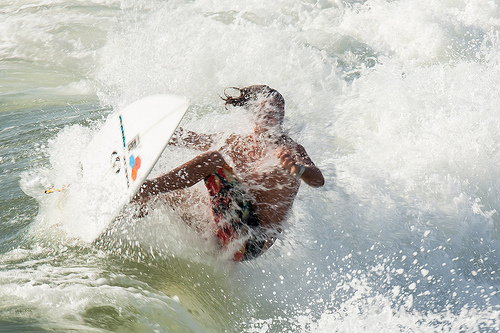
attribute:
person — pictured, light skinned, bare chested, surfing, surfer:
[128, 84, 328, 265]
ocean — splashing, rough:
[0, 0, 500, 333]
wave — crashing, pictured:
[100, 2, 499, 333]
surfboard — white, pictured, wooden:
[23, 90, 194, 251]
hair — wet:
[214, 81, 290, 117]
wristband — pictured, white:
[296, 162, 310, 178]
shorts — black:
[201, 160, 271, 263]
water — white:
[99, 0, 499, 231]